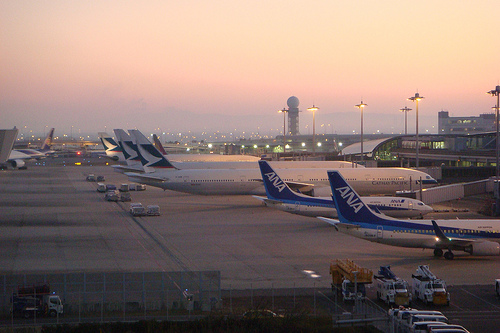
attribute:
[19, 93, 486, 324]
airport — large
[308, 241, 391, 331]
truck — white and yellow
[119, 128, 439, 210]
airplane — white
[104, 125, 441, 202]
commercial airplane — big, white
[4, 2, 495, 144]
sky — cloudy, hazy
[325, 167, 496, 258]
airplane — white